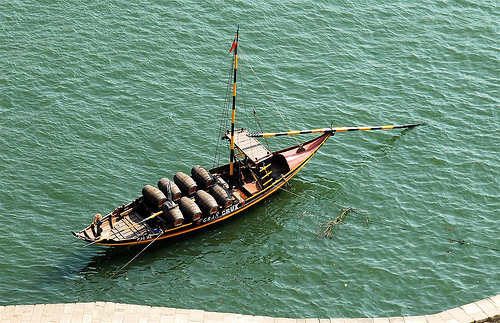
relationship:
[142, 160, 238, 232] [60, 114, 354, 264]
barrels are in sailboat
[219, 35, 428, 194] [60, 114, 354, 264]
poles on sailboat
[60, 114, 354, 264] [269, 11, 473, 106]
sailboat in water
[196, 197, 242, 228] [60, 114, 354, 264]
writing on sailboat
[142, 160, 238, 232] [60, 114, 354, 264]
items on sailboat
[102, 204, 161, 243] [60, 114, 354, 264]
platform on sailboat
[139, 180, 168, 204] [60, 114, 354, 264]
barrel on sailboat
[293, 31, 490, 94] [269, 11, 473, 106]
waves on water